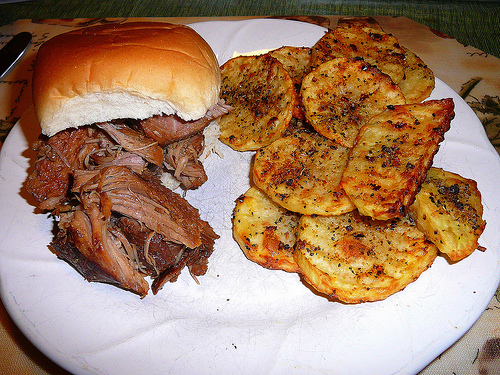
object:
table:
[0, 15, 497, 372]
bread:
[32, 21, 221, 137]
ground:
[428, 45, 500, 85]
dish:
[1, 18, 500, 375]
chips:
[219, 20, 487, 306]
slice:
[250, 133, 357, 215]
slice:
[299, 57, 406, 148]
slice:
[216, 53, 295, 152]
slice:
[267, 46, 312, 120]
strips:
[76, 123, 186, 280]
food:
[17, 21, 488, 305]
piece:
[342, 97, 455, 221]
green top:
[293, 3, 498, 56]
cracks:
[102, 203, 174, 294]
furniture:
[1, 0, 497, 375]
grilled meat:
[17, 98, 234, 300]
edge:
[408, 282, 499, 375]